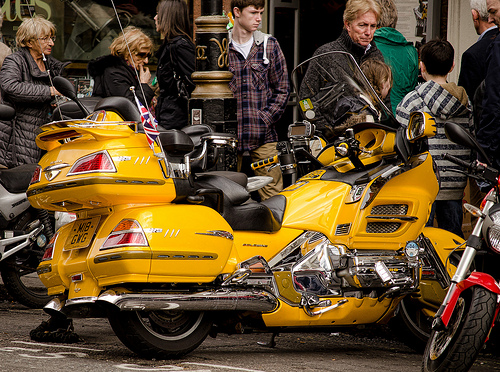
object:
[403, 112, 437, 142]
mirror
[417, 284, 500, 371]
wheel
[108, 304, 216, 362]
wheel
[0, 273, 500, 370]
parking space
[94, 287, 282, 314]
pipe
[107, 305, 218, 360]
tire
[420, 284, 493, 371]
tire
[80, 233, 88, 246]
letters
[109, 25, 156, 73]
head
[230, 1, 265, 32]
head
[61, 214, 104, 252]
license plate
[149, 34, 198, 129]
jacket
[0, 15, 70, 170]
person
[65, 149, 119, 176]
brake light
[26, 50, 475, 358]
bike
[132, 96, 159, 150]
flag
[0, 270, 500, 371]
street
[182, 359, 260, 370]
paint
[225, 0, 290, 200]
boy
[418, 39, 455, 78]
hair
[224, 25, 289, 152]
sweatshirt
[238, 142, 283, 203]
pants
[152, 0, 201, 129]
woman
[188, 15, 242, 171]
column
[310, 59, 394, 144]
girl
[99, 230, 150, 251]
tail light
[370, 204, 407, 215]
side vent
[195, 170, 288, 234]
seat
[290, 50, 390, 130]
windshield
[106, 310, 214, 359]
rear wheel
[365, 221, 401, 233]
vents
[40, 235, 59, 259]
light